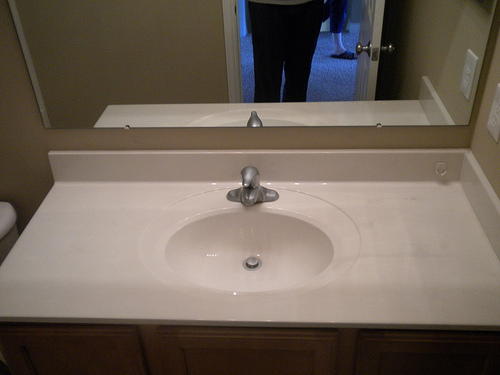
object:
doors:
[50, 316, 497, 374]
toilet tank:
[0, 199, 17, 250]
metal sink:
[177, 232, 317, 287]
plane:
[149, 202, 341, 298]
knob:
[378, 32, 397, 58]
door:
[341, 0, 398, 102]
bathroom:
[14, 142, 484, 364]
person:
[325, 2, 363, 58]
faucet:
[226, 163, 278, 206]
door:
[161, 329, 350, 374]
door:
[11, 326, 148, 373]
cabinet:
[0, 142, 499, 371]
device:
[434, 161, 446, 176]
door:
[355, 331, 497, 373]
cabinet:
[2, 320, 498, 373]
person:
[237, 0, 345, 113]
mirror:
[8, 1, 499, 130]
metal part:
[226, 165, 274, 206]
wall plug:
[481, 81, 499, 148]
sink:
[0, 149, 499, 325]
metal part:
[224, 158, 280, 275]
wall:
[1, 6, 484, 148]